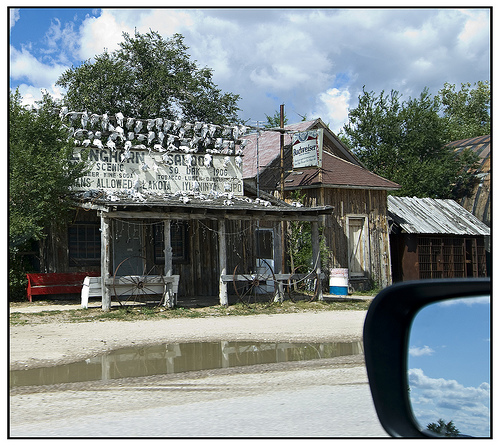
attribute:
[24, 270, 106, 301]
bench — Antique, red , wooden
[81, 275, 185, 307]
bench — red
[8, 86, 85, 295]
tree — overgrown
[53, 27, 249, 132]
tree — overgrown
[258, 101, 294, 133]
tree — overgrown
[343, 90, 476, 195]
tree — overgrown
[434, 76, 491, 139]
tree — overgrown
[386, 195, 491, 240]
roof — tin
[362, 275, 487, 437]
mirror — dark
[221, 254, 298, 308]
wheel — brown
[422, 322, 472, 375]
sky — blue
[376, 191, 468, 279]
building — brown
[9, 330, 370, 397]
puddle — Water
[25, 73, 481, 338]
building — Old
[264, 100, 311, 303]
wooden post — brown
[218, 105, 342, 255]
wooden post — white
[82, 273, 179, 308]
bench — white, wooden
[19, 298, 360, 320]
grass — green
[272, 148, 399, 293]
shack — Old, wooden